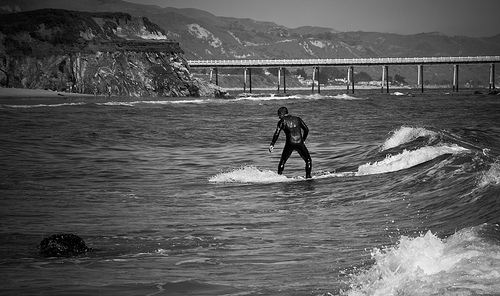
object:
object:
[36, 231, 94, 260]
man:
[268, 106, 313, 179]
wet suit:
[278, 115, 305, 143]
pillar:
[452, 65, 459, 92]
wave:
[353, 118, 498, 247]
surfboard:
[252, 170, 335, 181]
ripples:
[150, 254, 340, 296]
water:
[47, 180, 489, 293]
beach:
[0, 90, 192, 105]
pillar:
[278, 68, 287, 93]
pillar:
[209, 67, 219, 85]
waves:
[330, 67, 498, 272]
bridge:
[187, 55, 498, 92]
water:
[2, 63, 498, 294]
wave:
[403, 127, 486, 214]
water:
[68, 114, 169, 231]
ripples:
[45, 130, 229, 182]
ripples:
[123, 192, 245, 251]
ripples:
[362, 160, 448, 216]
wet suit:
[265, 113, 317, 175]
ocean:
[0, 99, 500, 296]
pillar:
[417, 66, 425, 93]